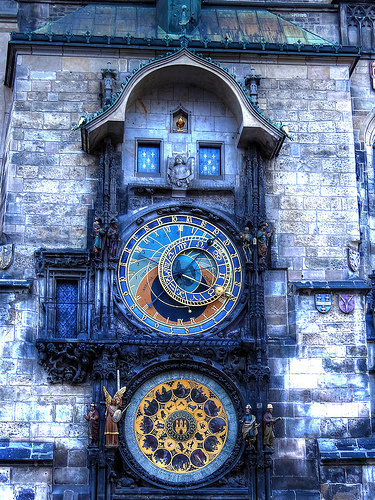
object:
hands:
[182, 273, 215, 290]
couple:
[314, 292, 356, 315]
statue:
[100, 382, 129, 446]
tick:
[136, 294, 142, 301]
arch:
[80, 40, 288, 161]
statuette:
[179, 112, 183, 119]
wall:
[0, 0, 375, 500]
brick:
[14, 402, 55, 423]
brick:
[55, 402, 75, 423]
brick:
[0, 420, 30, 442]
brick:
[38, 423, 70, 438]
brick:
[0, 400, 15, 422]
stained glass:
[138, 143, 159, 172]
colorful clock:
[121, 368, 241, 489]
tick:
[134, 245, 142, 254]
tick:
[153, 229, 159, 237]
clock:
[114, 210, 246, 339]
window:
[197, 139, 226, 180]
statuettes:
[83, 403, 101, 447]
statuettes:
[238, 402, 261, 452]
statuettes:
[261, 403, 282, 450]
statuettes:
[89, 216, 106, 262]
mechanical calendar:
[117, 213, 243, 334]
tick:
[190, 226, 194, 234]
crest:
[313, 292, 356, 315]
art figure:
[239, 226, 253, 264]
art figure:
[257, 221, 278, 265]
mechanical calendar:
[123, 369, 245, 487]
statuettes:
[107, 220, 121, 263]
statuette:
[166, 153, 196, 189]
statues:
[83, 401, 99, 446]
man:
[84, 401, 101, 449]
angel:
[101, 384, 132, 447]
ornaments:
[171, 379, 191, 400]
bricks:
[348, 418, 372, 437]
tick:
[177, 224, 183, 231]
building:
[0, 0, 375, 500]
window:
[135, 137, 164, 176]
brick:
[310, 388, 353, 403]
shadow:
[0, 352, 320, 500]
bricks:
[284, 185, 320, 197]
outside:
[0, 0, 375, 500]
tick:
[190, 317, 196, 325]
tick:
[218, 296, 226, 304]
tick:
[127, 271, 135, 276]